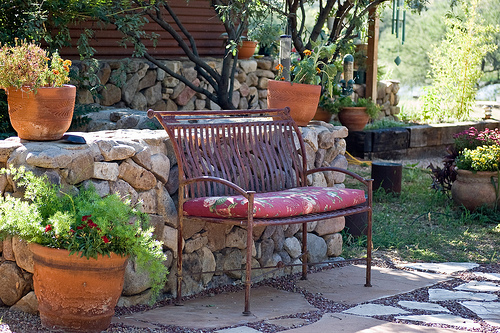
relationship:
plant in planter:
[433, 134, 496, 214] [449, 168, 499, 222]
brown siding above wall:
[37, 0, 247, 59] [112, 53, 228, 110]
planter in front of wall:
[35, 223, 130, 330] [7, 129, 355, 305]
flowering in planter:
[0, 165, 170, 309] [35, 223, 130, 330]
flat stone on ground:
[297, 262, 454, 303] [0, 165, 498, 331]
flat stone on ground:
[116, 282, 325, 329] [0, 165, 498, 331]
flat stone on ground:
[398, 297, 448, 313] [0, 165, 498, 331]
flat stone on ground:
[427, 285, 498, 302] [0, 165, 498, 331]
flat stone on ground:
[279, 308, 464, 331] [0, 165, 498, 331]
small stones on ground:
[1, 305, 44, 332] [0, 165, 498, 331]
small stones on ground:
[309, 270, 499, 330] [0, 165, 498, 331]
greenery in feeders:
[272, 41, 342, 83] [267, 79, 322, 127]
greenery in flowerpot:
[0, 43, 71, 85] [6, 83, 76, 140]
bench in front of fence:
[146, 106, 376, 316] [0, 121, 349, 313]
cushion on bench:
[185, 173, 367, 220] [146, 106, 376, 316]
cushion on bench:
[183, 186, 367, 219] [146, 106, 376, 316]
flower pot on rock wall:
[236, 38, 258, 57] [68, 57, 273, 115]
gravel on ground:
[50, 114, 172, 233] [0, 165, 498, 331]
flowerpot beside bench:
[13, 62, 80, 162] [146, 106, 376, 316]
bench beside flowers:
[146, 106, 376, 316] [452, 123, 499, 147]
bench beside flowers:
[146, 106, 376, 316] [277, 46, 318, 82]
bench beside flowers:
[146, 106, 376, 316] [42, 208, 111, 245]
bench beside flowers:
[146, 106, 376, 316] [1, 42, 76, 87]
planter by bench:
[26, 242, 130, 333] [146, 106, 376, 316]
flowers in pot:
[39, 210, 114, 252] [26, 232, 123, 331]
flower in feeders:
[302, 51, 312, 60] [267, 79, 322, 127]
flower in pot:
[26, 215, 161, 275] [31, 234, 124, 324]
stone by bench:
[103, 155, 156, 193] [153, 92, 388, 294]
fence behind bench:
[0, 121, 349, 313] [121, 96, 386, 301]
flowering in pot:
[0, 165, 170, 309] [26, 232, 123, 331]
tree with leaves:
[0, 0, 252, 109] [115, 1, 146, 79]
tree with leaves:
[0, 0, 252, 109] [59, 25, 103, 112]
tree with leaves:
[0, 0, 252, 109] [1, 0, 51, 52]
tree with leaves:
[0, 0, 500, 121] [477, 21, 498, 35]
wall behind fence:
[38, 10, 240, 82] [0, 74, 453, 282]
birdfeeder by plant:
[278, 34, 294, 84] [289, 42, 336, 85]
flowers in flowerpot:
[0, 37, 73, 86] [6, 83, 76, 140]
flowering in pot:
[0, 165, 170, 309] [27, 245, 131, 331]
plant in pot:
[265, 47, 327, 82] [265, 78, 316, 119]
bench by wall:
[143, 75, 404, 296] [11, 122, 381, 274]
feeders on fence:
[267, 79, 322, 127] [0, 121, 349, 313]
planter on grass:
[445, 163, 498, 213] [329, 128, 490, 268]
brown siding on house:
[50, 3, 250, 54] [41, 1, 278, 129]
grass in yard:
[367, 179, 472, 281] [52, 37, 499, 299]